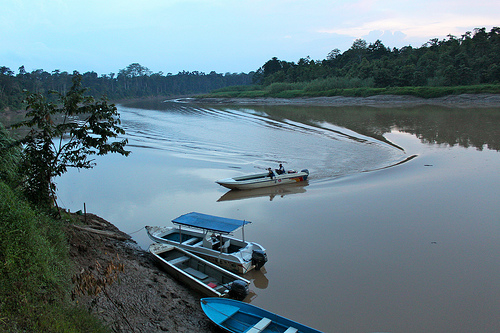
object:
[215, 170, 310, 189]
boat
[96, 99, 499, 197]
water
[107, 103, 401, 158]
wake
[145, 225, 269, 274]
boat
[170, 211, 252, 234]
canopy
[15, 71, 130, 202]
trees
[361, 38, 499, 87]
leaves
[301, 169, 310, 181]
engine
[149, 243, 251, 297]
boat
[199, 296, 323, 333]
boats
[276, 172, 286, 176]
seat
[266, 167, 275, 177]
people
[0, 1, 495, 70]
sky